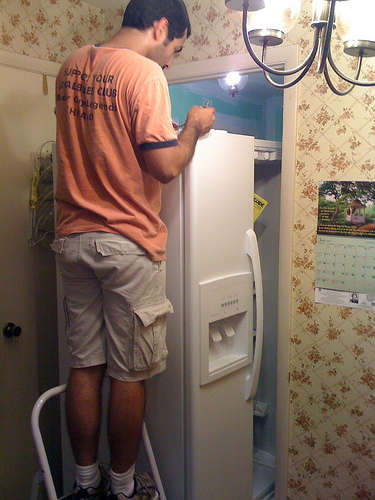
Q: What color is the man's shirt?
A: Orange.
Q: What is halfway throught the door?
A: A refrigerator.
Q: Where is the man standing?
A: On a step ladder.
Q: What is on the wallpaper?
A: Flowers.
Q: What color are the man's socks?
A: White.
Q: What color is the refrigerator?
A: White.